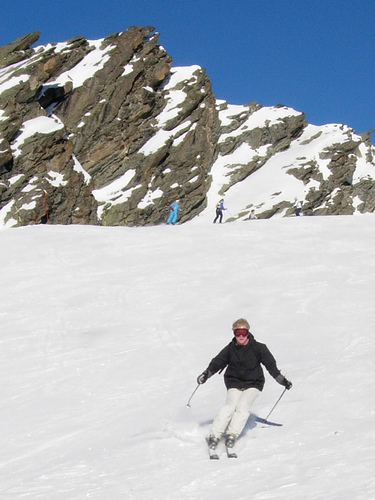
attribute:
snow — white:
[2, 213, 373, 499]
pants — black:
[213, 208, 224, 221]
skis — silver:
[203, 431, 240, 462]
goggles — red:
[233, 328, 249, 335]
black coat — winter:
[204, 336, 285, 389]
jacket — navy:
[202, 330, 285, 391]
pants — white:
[207, 390, 260, 445]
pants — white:
[203, 369, 272, 450]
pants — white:
[210, 388, 259, 436]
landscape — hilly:
[2, 25, 374, 496]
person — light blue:
[167, 195, 179, 223]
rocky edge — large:
[8, 37, 237, 217]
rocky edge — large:
[252, 100, 373, 209]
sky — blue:
[0, 0, 373, 146]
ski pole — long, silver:
[262, 385, 286, 431]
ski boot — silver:
[225, 432, 236, 456]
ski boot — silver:
[206, 432, 219, 452]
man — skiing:
[137, 287, 302, 461]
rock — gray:
[1, 24, 221, 226]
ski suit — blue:
[163, 201, 182, 222]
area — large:
[2, 209, 364, 496]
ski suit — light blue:
[172, 200, 180, 219]